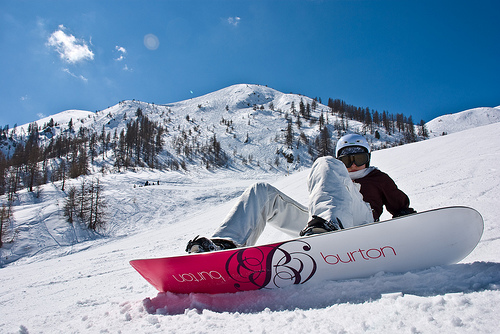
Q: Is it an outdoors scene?
A: Yes, it is outdoors.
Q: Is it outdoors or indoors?
A: It is outdoors.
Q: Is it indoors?
A: No, it is outdoors.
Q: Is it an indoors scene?
A: No, it is outdoors.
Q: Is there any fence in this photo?
A: No, there are no fences.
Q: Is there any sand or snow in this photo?
A: Yes, there is snow.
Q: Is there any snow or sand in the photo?
A: Yes, there is snow.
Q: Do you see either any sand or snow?
A: Yes, there is snow.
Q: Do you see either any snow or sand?
A: Yes, there is snow.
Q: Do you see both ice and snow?
A: No, there is snow but no ice.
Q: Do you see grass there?
A: No, there is no grass.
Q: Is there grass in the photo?
A: No, there is no grass.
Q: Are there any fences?
A: No, there are no fences.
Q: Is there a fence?
A: No, there are no fences.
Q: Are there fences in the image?
A: No, there are no fences.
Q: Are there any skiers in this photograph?
A: No, there are no skiers.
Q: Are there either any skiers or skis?
A: No, there are no skiers or skis.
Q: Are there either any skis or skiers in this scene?
A: No, there are no skiers or skis.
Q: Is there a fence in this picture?
A: No, there are no fences.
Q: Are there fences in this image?
A: No, there are no fences.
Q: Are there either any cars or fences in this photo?
A: No, there are no fences or cars.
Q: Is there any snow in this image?
A: Yes, there is snow.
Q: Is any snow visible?
A: Yes, there is snow.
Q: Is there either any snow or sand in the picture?
A: Yes, there is snow.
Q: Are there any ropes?
A: No, there are no ropes.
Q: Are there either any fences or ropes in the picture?
A: No, there are no ropes or fences.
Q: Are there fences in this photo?
A: No, there are no fences.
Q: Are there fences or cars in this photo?
A: No, there are no fences or cars.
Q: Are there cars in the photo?
A: No, there are no cars.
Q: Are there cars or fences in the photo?
A: No, there are no cars or fences.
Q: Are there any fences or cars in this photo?
A: No, there are no cars or fences.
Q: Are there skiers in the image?
A: No, there are no skiers.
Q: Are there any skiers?
A: No, there are no skiers.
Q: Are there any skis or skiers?
A: No, there are no skiers or skis.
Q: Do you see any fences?
A: No, there are no fences.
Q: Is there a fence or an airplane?
A: No, there are no fences or airplanes.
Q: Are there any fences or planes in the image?
A: No, there are no fences or planes.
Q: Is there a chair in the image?
A: Yes, there is a chair.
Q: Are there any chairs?
A: Yes, there is a chair.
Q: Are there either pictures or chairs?
A: Yes, there is a chair.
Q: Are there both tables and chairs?
A: No, there is a chair but no tables.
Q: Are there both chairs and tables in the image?
A: No, there is a chair but no tables.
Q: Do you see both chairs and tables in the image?
A: No, there is a chair but no tables.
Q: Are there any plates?
A: No, there are no plates.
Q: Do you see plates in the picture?
A: No, there are no plates.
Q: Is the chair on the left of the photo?
A: No, the chair is on the right of the image.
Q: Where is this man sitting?
A: The man is sitting in the snow.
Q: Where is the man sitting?
A: The man is sitting in the snow.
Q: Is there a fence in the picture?
A: No, there are no fences.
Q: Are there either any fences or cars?
A: No, there are no fences or cars.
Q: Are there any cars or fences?
A: No, there are no cars or fences.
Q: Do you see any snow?
A: Yes, there is snow.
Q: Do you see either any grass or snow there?
A: Yes, there is snow.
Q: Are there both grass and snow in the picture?
A: No, there is snow but no grass.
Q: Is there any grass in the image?
A: No, there is no grass.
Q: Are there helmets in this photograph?
A: Yes, there is a helmet.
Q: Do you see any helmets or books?
A: Yes, there is a helmet.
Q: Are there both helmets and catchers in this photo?
A: No, there is a helmet but no catchers.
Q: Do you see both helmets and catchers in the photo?
A: No, there is a helmet but no catchers.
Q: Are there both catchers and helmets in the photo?
A: No, there is a helmet but no catchers.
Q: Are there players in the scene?
A: No, there are no players.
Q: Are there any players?
A: No, there are no players.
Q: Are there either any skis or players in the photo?
A: No, there are no players or skis.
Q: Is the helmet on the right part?
A: Yes, the helmet is on the right of the image.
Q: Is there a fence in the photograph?
A: No, there are no fences.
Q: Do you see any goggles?
A: Yes, there are goggles.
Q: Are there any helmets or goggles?
A: Yes, there are goggles.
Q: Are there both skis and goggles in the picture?
A: No, there are goggles but no skis.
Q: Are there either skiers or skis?
A: No, there are no skis or skiers.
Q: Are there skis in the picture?
A: No, there are no skis.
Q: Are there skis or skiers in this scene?
A: No, there are no skis or skiers.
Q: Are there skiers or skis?
A: No, there are no skis or skiers.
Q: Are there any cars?
A: No, there are no cars.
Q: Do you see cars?
A: No, there are no cars.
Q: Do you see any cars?
A: No, there are no cars.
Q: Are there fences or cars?
A: No, there are no cars or fences.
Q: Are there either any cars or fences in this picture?
A: No, there are no cars or fences.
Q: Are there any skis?
A: No, there are no skis.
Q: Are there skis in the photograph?
A: No, there are no skis.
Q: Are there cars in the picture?
A: No, there are no cars.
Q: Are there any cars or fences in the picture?
A: No, there are no cars or fences.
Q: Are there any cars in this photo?
A: No, there are no cars.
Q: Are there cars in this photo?
A: No, there are no cars.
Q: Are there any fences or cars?
A: No, there are no cars or fences.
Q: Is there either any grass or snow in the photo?
A: Yes, there is snow.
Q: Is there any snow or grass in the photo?
A: Yes, there is snow.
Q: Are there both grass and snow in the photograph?
A: No, there is snow but no grass.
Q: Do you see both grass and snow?
A: No, there is snow but no grass.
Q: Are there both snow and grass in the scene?
A: No, there is snow but no grass.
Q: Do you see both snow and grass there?
A: No, there is snow but no grass.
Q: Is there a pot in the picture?
A: No, there are no pots.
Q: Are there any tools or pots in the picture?
A: No, there are no pots or tools.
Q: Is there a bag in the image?
A: No, there are no bags.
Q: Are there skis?
A: No, there are no skis.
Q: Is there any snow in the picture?
A: Yes, there is snow.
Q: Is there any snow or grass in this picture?
A: Yes, there is snow.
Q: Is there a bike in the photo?
A: No, there are no bikes.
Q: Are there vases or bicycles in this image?
A: No, there are no bicycles or vases.